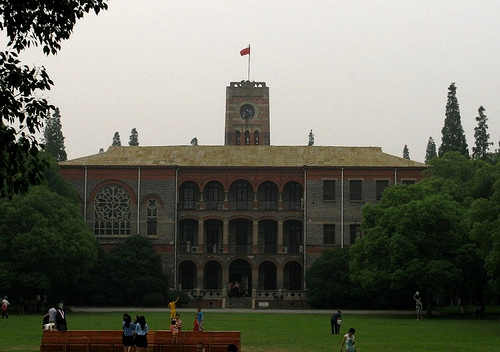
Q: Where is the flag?
A: At the top of the building.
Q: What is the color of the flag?
A: Red.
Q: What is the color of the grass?
A: Green.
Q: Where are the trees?
A: In front of the building.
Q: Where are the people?
A: On the field.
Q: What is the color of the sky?
A: Gray.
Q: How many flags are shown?
A: One.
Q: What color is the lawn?
A: Green.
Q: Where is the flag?
A: On top of the clock tower.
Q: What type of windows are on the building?
A: Arched windows.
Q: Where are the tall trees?
A: Surrounding the building.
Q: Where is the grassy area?
A: In front of the building.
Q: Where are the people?
A: On the grassy area.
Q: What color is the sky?
A: Overcast.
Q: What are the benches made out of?
A: Wood.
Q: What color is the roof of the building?
A: Tan.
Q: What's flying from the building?
A: Flag.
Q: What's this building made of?
A: Stone.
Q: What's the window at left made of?
A: Stained glass.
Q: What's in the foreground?
A: Grassy field.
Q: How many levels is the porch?
A: Three.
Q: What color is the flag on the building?
A: Red.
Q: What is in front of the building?
A: A lawn.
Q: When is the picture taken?
A: Daytime.